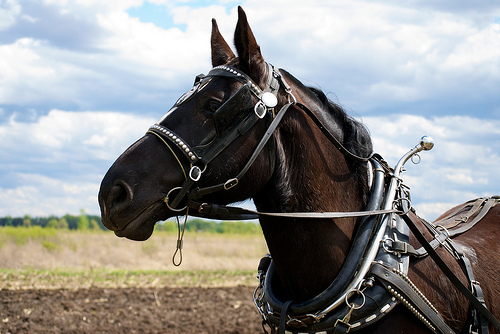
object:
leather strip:
[148, 124, 204, 171]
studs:
[150, 122, 195, 160]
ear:
[209, 5, 259, 65]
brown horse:
[97, 5, 500, 334]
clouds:
[0, 0, 496, 215]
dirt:
[1, 284, 326, 332]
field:
[3, 237, 254, 282]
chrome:
[394, 135, 434, 175]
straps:
[166, 66, 284, 214]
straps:
[148, 119, 200, 182]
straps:
[188, 207, 392, 219]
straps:
[261, 62, 286, 99]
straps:
[395, 197, 457, 281]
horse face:
[97, 66, 252, 215]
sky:
[0, 0, 498, 220]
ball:
[420, 135, 435, 152]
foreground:
[5, 0, 496, 320]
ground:
[8, 278, 282, 330]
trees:
[3, 210, 251, 230]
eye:
[202, 99, 226, 114]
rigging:
[252, 154, 480, 334]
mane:
[274, 67, 372, 166]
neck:
[251, 77, 371, 276]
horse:
[95, 3, 500, 334]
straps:
[146, 60, 391, 232]